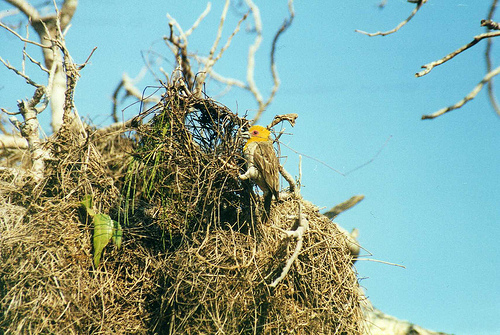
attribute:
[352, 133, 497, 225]
sky — blue, clear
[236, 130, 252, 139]
beak — small, pointy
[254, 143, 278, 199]
feathers — dark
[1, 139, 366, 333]
grass — dry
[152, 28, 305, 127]
branches — dry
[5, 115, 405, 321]
grass — dead, clumped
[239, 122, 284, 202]
bird — brown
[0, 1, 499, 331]
sky — blue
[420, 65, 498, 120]
branch — leafless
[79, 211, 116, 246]
green leaf — bright green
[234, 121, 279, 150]
head — yellow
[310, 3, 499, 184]
sky — bright blue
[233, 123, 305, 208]
bird — yellow, sitting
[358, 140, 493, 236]
sky — clear, blue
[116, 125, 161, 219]
grass — Green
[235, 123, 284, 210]
bird — yellow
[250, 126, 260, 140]
eye — black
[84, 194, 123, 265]
leaf — green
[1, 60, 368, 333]
weed grass — weed , bunch 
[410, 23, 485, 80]
branch — tree